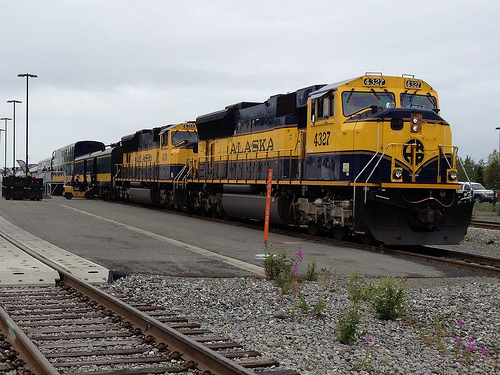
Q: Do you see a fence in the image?
A: No, there are no fences.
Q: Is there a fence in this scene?
A: No, there are no fences.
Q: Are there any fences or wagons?
A: No, there are no fences or wagons.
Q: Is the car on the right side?
A: Yes, the car is on the right of the image.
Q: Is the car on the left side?
A: No, the car is on the right of the image.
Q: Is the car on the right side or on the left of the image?
A: The car is on the right of the image.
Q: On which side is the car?
A: The car is on the right of the image.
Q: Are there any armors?
A: No, there are no armors.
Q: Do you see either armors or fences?
A: No, there are no armors or fences.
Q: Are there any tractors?
A: No, there are no tractors.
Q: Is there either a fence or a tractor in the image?
A: No, there are no tractors or fences.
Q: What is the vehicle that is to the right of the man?
A: The vehicle is a train car.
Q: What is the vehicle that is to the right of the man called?
A: The vehicle is a train car.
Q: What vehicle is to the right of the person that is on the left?
A: The vehicle is a train car.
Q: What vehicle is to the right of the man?
A: The vehicle is a train car.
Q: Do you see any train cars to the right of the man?
A: Yes, there is a train car to the right of the man.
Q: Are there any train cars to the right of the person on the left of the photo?
A: Yes, there is a train car to the right of the man.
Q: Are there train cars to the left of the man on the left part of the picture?
A: No, the train car is to the right of the man.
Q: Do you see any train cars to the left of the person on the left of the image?
A: No, the train car is to the right of the man.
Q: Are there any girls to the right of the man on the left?
A: No, there is a train car to the right of the man.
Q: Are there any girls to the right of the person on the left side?
A: No, there is a train car to the right of the man.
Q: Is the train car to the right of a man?
A: Yes, the train car is to the right of a man.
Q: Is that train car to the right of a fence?
A: No, the train car is to the right of a man.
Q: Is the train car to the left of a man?
A: No, the train car is to the right of a man.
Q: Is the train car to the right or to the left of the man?
A: The train car is to the right of the man.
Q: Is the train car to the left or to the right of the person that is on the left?
A: The train car is to the right of the man.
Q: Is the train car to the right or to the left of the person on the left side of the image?
A: The train car is to the right of the man.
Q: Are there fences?
A: No, there are no fences.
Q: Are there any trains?
A: Yes, there is a train.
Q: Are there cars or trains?
A: Yes, there is a train.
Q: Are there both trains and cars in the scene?
A: Yes, there are both a train and a car.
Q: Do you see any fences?
A: No, there are no fences.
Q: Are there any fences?
A: No, there are no fences.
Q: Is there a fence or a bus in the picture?
A: No, there are no fences or buses.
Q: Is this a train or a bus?
A: This is a train.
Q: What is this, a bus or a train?
A: This is a train.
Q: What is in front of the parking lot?
A: The train is in front of the parking lot.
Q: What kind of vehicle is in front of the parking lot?
A: The vehicle is a train.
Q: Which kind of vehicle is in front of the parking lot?
A: The vehicle is a train.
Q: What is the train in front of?
A: The train is in front of the parking lot.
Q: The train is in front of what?
A: The train is in front of the parking lot.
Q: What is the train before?
A: The train is in front of the parking lot.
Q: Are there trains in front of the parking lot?
A: Yes, there is a train in front of the parking lot.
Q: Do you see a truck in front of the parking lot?
A: No, there is a train in front of the parking lot.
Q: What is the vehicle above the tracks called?
A: The vehicle is a train.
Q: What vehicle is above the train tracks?
A: The vehicle is a train.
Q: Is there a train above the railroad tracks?
A: Yes, there is a train above the railroad tracks.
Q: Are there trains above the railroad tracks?
A: Yes, there is a train above the railroad tracks.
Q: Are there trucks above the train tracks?
A: No, there is a train above the train tracks.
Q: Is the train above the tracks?
A: Yes, the train is above the tracks.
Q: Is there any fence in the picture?
A: No, there are no fences.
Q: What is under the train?
A: The train tracks are under the train.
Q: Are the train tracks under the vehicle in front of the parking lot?
A: Yes, the train tracks are under the train.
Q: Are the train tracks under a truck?
A: No, the train tracks are under the train.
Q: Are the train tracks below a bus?
A: No, the train tracks are below the train.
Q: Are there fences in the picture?
A: No, there are no fences.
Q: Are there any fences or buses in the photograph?
A: No, there are no fences or buses.